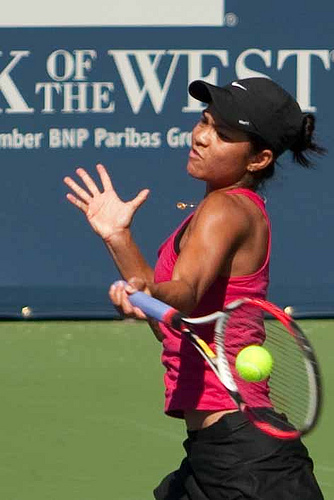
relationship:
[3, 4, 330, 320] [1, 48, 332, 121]
banner says bank of west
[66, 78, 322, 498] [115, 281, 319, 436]
woman holding racquet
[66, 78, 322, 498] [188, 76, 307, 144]
woman wearing cap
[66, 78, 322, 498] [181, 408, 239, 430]
player has stomach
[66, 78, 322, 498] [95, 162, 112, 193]
player has finger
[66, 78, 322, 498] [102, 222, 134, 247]
player has wrist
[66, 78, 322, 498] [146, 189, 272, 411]
player in pink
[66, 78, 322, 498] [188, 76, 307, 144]
woman wears hat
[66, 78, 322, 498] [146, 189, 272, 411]
woman wears tank top